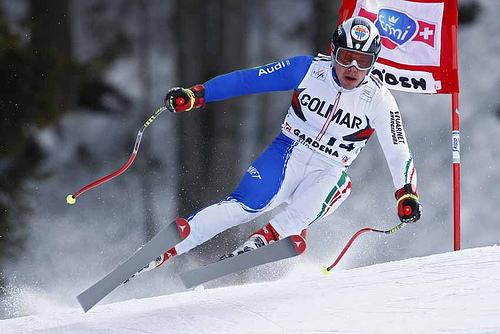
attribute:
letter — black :
[305, 95, 321, 115]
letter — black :
[315, 99, 334, 118]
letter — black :
[310, 93, 318, 112]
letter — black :
[338, 117, 350, 130]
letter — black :
[348, 114, 361, 134]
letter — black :
[288, 120, 302, 143]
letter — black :
[302, 129, 305, 144]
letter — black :
[305, 136, 322, 138]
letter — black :
[310, 137, 319, 153]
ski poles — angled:
[39, 95, 195, 215]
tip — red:
[155, 213, 195, 243]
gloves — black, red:
[164, 83, 431, 241]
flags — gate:
[333, 3, 469, 255]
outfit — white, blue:
[150, 50, 422, 255]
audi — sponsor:
[253, 55, 293, 84]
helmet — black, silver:
[324, 14, 382, 72]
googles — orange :
[322, 39, 378, 75]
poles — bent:
[52, 81, 421, 281]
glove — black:
[157, 83, 206, 121]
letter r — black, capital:
[348, 112, 369, 133]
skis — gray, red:
[72, 208, 308, 318]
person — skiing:
[210, 15, 452, 321]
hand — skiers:
[154, 72, 204, 128]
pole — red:
[434, 115, 481, 211]